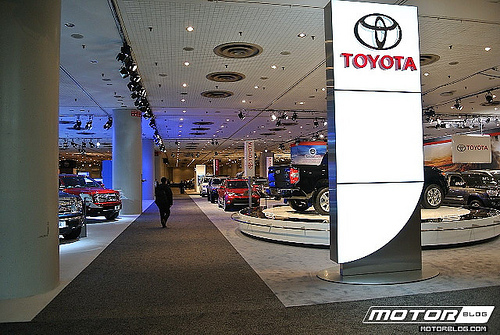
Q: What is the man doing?
A: Walking.